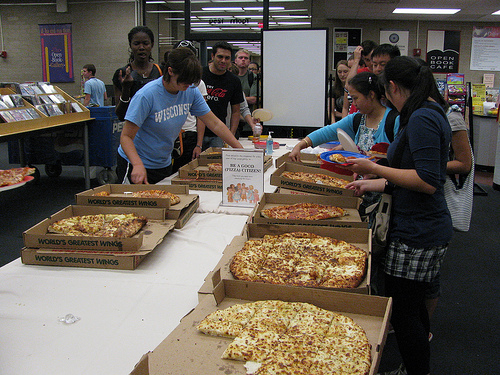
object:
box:
[22, 204, 166, 251]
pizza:
[194, 297, 370, 374]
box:
[126, 277, 393, 374]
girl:
[342, 56, 455, 372]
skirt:
[384, 236, 447, 284]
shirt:
[117, 74, 212, 170]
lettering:
[154, 101, 190, 125]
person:
[234, 49, 257, 135]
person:
[198, 41, 243, 150]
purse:
[444, 105, 476, 233]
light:
[394, 8, 462, 15]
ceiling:
[313, 2, 499, 25]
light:
[492, 10, 500, 18]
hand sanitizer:
[266, 130, 276, 153]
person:
[288, 71, 405, 171]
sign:
[426, 44, 461, 73]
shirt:
[201, 65, 245, 138]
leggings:
[387, 277, 433, 372]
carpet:
[2, 177, 99, 263]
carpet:
[374, 181, 500, 370]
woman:
[115, 45, 241, 185]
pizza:
[193, 161, 222, 176]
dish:
[321, 150, 375, 167]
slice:
[330, 152, 347, 162]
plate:
[336, 128, 359, 152]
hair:
[161, 47, 202, 88]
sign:
[219, 147, 268, 208]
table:
[155, 136, 355, 217]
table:
[0, 137, 289, 374]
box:
[20, 244, 141, 270]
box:
[205, 223, 378, 290]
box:
[252, 192, 370, 225]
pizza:
[50, 214, 145, 240]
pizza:
[230, 231, 367, 290]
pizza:
[260, 199, 348, 222]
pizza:
[280, 169, 354, 191]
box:
[267, 159, 367, 194]